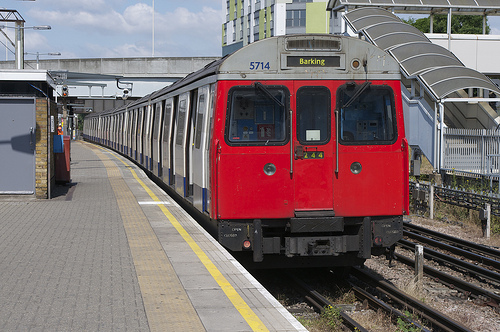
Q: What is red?
A: The front of the train.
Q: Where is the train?
A: On the track.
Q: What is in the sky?
A: Clouds.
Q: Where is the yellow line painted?
A: On the landing above the tracks.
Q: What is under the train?
A: Tracks.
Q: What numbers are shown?
A: 5714.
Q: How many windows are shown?
A: Three.